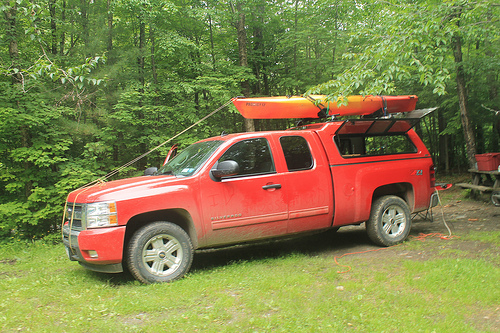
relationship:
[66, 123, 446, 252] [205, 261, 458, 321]
truck on grass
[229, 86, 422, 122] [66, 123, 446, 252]
canoe on truck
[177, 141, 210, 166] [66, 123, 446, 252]
windshield on truck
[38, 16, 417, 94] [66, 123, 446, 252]
woods behind truck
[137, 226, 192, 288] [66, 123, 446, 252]
tire on truck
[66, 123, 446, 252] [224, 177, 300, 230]
truck has door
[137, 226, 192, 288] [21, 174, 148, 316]
tire in front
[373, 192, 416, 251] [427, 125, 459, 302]
tire in rear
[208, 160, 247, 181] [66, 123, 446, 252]
mirror on truck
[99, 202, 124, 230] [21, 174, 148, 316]
headlight in front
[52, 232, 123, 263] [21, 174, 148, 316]
fender in front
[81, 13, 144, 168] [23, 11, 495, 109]
tree in background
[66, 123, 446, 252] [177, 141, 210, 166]
truck has windshield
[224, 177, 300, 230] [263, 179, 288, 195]
door has handle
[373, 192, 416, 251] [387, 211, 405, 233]
tire has hubcap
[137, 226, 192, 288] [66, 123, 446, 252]
wheel on truck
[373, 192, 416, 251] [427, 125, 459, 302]
wheel in rear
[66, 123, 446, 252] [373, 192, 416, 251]
truck has wheel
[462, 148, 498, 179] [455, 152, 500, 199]
basket on table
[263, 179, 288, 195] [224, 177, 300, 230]
handle on door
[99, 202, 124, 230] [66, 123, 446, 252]
headlight on truck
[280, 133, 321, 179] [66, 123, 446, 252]
window on truck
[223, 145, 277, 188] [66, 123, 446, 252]
window on truck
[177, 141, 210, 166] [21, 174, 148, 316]
windshield in front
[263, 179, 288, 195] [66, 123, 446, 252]
handle on truck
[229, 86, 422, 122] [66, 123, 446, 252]
kayak on truck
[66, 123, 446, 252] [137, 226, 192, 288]
truck has tire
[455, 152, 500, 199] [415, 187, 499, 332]
table on ground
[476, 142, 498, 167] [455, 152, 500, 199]
bin on table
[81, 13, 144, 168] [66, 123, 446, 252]
tree behind truck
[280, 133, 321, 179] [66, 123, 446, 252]
window on vehicle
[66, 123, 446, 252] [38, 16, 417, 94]
truck in woods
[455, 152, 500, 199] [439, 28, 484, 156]
table beside tree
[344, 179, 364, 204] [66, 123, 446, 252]
tank on truck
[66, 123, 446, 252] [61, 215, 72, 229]
truck has logo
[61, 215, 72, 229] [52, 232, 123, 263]
logo on fender